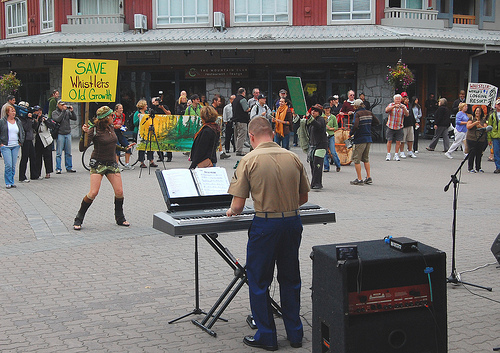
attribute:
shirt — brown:
[221, 138, 313, 218]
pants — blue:
[228, 219, 332, 309]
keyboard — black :
[151, 179, 333, 230]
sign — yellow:
[61, 57, 119, 104]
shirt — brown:
[227, 137, 322, 224]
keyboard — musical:
[142, 157, 347, 234]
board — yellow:
[61, 60, 112, 106]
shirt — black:
[303, 112, 332, 151]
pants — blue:
[239, 210, 304, 351]